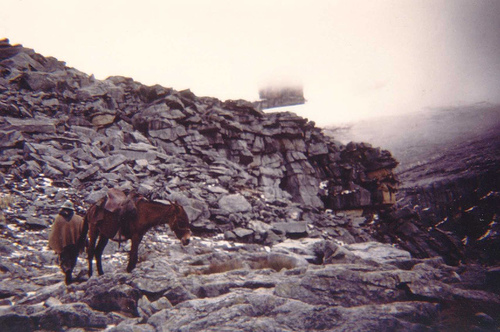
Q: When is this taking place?
A: Daytime.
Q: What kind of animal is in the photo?
A: Horse.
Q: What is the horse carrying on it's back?
A: Bag.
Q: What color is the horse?
A: Brown.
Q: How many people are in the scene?
A: One.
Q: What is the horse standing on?
A: Rocks.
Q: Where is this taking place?
A: Near the cliff.